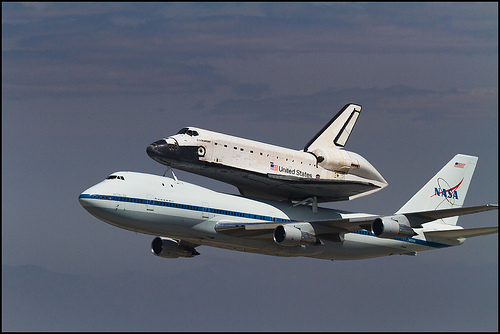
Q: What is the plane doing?
A: Carrying a space shuttle.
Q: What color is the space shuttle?
A: White.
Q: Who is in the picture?
A: There are no people in the picture.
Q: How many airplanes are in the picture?
A: One.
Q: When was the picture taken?
A: During the day.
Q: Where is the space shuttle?
A: On top of the plane.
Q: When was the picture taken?
A: While the plane was carrying the space shuttle.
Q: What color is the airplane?
A: Blue.